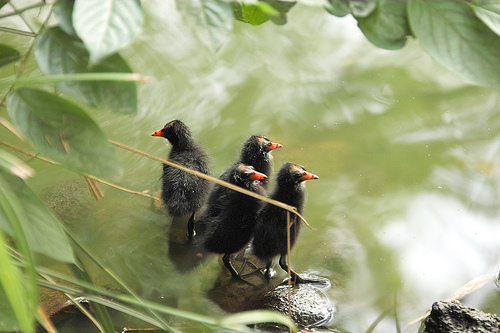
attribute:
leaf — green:
[173, 0, 236, 58]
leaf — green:
[76, 0, 144, 67]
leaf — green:
[320, 0, 355, 19]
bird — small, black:
[250, 158, 320, 293]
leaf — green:
[1, 77, 130, 222]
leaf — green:
[321, 2, 498, 102]